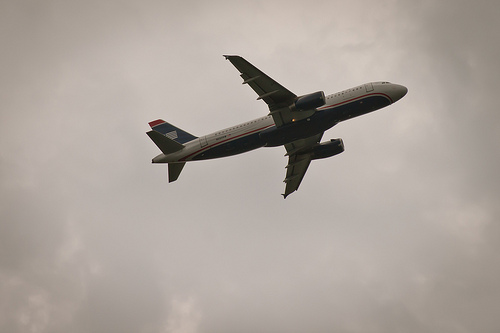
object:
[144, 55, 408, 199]
airplane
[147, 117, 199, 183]
tail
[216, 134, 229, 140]
writing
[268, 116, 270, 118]
windows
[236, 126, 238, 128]
window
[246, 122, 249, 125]
window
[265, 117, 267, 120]
window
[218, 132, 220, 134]
window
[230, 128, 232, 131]
window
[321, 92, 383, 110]
line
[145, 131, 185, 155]
small wings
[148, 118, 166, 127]
tip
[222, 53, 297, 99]
wing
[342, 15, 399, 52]
gray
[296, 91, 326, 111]
engine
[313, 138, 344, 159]
engine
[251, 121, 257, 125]
windows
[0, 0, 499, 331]
sky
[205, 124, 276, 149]
red stripe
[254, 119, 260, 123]
windows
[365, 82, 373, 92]
door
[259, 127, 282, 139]
cylinder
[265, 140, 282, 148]
cylinder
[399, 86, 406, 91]
nose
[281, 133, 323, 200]
wing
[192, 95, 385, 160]
bottom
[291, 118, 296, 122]
light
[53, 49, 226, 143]
overcast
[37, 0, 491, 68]
air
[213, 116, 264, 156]
passengers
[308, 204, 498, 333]
cloud cover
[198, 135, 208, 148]
back door